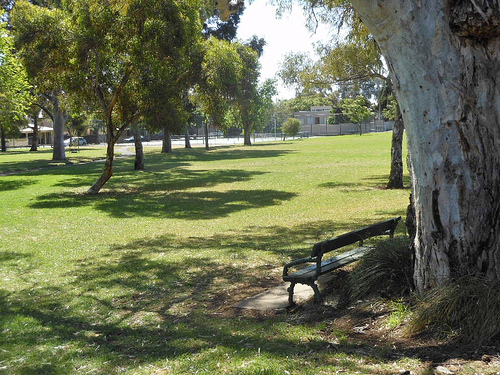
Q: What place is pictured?
A: It is a park.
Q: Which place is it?
A: It is a park.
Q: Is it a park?
A: Yes, it is a park.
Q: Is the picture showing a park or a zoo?
A: It is showing a park.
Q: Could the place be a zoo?
A: No, it is a park.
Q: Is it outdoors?
A: Yes, it is outdoors.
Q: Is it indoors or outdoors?
A: It is outdoors.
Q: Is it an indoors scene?
A: No, it is outdoors.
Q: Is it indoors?
A: No, it is outdoors.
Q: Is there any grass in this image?
A: Yes, there is grass.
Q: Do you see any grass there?
A: Yes, there is grass.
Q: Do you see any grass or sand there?
A: Yes, there is grass.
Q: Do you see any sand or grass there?
A: Yes, there is grass.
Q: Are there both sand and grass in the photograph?
A: No, there is grass but no sand.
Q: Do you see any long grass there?
A: Yes, there is long grass.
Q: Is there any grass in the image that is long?
A: Yes, there is grass that is long.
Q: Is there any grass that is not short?
A: Yes, there is long grass.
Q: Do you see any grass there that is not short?
A: Yes, there is long grass.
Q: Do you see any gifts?
A: No, there are no gifts.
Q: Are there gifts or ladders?
A: No, there are no gifts or ladders.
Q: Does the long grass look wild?
A: Yes, the grass is wild.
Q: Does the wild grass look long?
A: Yes, the grass is long.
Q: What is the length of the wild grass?
A: The grass is long.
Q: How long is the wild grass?
A: The grass is long.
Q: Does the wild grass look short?
A: No, the grass is long.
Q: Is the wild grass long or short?
A: The grass is long.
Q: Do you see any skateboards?
A: No, there are no skateboards.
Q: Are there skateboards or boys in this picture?
A: No, there are no skateboards or boys.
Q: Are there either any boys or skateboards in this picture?
A: No, there are no skateboards or boys.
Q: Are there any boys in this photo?
A: No, there are no boys.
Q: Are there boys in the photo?
A: No, there are no boys.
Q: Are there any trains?
A: No, there are no trains.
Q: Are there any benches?
A: Yes, there is a bench.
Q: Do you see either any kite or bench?
A: Yes, there is a bench.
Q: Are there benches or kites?
A: Yes, there is a bench.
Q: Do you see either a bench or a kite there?
A: Yes, there is a bench.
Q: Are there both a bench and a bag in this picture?
A: No, there is a bench but no bags.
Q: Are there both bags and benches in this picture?
A: No, there is a bench but no bags.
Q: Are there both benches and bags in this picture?
A: No, there is a bench but no bags.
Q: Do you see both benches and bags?
A: No, there is a bench but no bags.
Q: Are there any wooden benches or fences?
A: Yes, there is a wood bench.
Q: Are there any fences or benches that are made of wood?
A: Yes, the bench is made of wood.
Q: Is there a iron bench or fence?
A: Yes, there is an iron bench.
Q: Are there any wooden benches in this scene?
A: Yes, there is a wood bench.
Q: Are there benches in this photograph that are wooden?
A: Yes, there is a bench that is wooden.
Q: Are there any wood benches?
A: Yes, there is a bench that is made of wood.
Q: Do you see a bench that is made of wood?
A: Yes, there is a bench that is made of wood.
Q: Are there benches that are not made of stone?
A: Yes, there is a bench that is made of wood.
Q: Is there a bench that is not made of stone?
A: Yes, there is a bench that is made of wood.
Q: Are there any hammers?
A: No, there are no hammers.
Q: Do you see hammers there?
A: No, there are no hammers.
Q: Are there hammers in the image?
A: No, there are no hammers.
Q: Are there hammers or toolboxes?
A: No, there are no hammers or toolboxes.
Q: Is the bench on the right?
A: Yes, the bench is on the right of the image.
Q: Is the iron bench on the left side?
A: No, the bench is on the right of the image.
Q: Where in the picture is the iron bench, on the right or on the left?
A: The bench is on the right of the image.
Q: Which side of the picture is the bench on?
A: The bench is on the right of the image.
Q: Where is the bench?
A: The bench is in the park.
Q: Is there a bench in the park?
A: Yes, there is a bench in the park.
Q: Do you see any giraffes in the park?
A: No, there is a bench in the park.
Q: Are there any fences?
A: Yes, there is a fence.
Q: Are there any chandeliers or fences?
A: Yes, there is a fence.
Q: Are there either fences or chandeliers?
A: Yes, there is a fence.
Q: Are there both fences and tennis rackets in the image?
A: No, there is a fence but no rackets.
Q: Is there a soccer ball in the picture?
A: No, there are no soccer balls.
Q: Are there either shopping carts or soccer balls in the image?
A: No, there are no soccer balls or shopping carts.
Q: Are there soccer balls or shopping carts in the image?
A: No, there are no soccer balls or shopping carts.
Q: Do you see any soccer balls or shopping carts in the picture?
A: No, there are no soccer balls or shopping carts.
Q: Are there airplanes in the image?
A: No, there are no airplanes.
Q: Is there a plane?
A: No, there are no airplanes.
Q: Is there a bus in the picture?
A: No, there are no buses.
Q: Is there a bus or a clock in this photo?
A: No, there are no buses or clocks.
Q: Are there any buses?
A: No, there are no buses.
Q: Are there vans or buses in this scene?
A: No, there are no buses or vans.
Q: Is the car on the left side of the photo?
A: Yes, the car is on the left of the image.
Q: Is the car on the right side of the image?
A: No, the car is on the left of the image.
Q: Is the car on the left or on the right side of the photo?
A: The car is on the left of the image.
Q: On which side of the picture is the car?
A: The car is on the left of the image.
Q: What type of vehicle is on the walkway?
A: The vehicle is a car.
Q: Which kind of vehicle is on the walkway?
A: The vehicle is a car.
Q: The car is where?
A: The car is on the walkway.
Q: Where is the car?
A: The car is on the walkway.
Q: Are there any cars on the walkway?
A: Yes, there is a car on the walkway.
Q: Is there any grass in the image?
A: Yes, there is grass.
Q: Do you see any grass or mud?
A: Yes, there is grass.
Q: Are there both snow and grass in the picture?
A: No, there is grass but no snow.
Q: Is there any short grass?
A: Yes, there is short grass.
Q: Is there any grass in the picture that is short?
A: Yes, there is grass that is short.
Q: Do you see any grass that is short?
A: Yes, there is grass that is short.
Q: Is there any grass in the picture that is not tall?
A: Yes, there is short grass.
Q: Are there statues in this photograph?
A: No, there are no statues.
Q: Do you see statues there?
A: No, there are no statues.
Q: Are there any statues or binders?
A: No, there are no statues or binders.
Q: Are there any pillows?
A: No, there are no pillows.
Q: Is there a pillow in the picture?
A: No, there are no pillows.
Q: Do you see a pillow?
A: No, there are no pillows.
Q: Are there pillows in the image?
A: No, there are no pillows.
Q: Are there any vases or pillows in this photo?
A: No, there are no pillows or vases.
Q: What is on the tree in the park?
A: The leaves are on the tree.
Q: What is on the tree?
A: The leaves are on the tree.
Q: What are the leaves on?
A: The leaves are on the tree.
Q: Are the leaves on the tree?
A: Yes, the leaves are on the tree.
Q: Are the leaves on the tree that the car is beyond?
A: Yes, the leaves are on the tree.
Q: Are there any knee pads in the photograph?
A: No, there are no knee pads.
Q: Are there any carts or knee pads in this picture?
A: No, there are no knee pads or carts.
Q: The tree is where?
A: The tree is in the park.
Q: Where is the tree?
A: The tree is in the park.